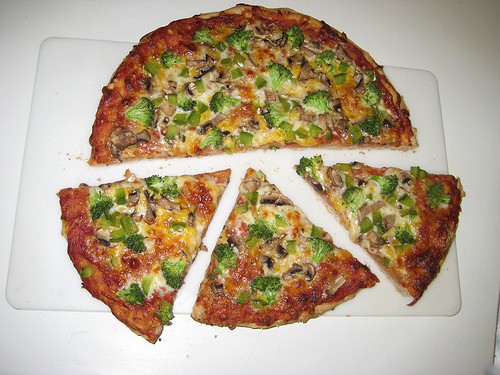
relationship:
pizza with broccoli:
[299, 157, 459, 304] [371, 172, 399, 195]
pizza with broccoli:
[299, 157, 459, 304] [426, 180, 451, 205]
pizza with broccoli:
[299, 157, 459, 304] [343, 185, 364, 209]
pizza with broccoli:
[299, 157, 459, 304] [300, 156, 320, 178]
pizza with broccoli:
[299, 157, 459, 304] [397, 226, 413, 246]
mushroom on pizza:
[306, 262, 316, 281] [190, 167, 380, 329]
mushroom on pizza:
[262, 238, 287, 258] [190, 167, 380, 329]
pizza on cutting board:
[299, 157, 459, 304] [5, 34, 462, 319]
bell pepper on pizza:
[186, 112, 202, 129] [75, 4, 407, 168]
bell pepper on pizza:
[167, 93, 180, 106] [75, 4, 407, 168]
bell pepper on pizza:
[144, 61, 160, 75] [75, 4, 407, 168]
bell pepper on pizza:
[163, 125, 179, 140] [75, 4, 407, 168]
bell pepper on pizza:
[195, 77, 204, 95] [75, 4, 407, 168]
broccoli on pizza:
[300, 156, 320, 178] [299, 157, 459, 304]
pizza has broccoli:
[299, 157, 459, 304] [343, 185, 364, 209]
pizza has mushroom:
[190, 167, 380, 329] [306, 262, 316, 281]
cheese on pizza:
[148, 215, 177, 251] [54, 166, 230, 343]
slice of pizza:
[30, 147, 218, 345] [54, 166, 230, 343]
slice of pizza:
[190, 167, 380, 329] [58, 5, 465, 347]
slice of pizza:
[301, 147, 467, 295] [58, 5, 465, 347]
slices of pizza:
[205, 142, 471, 344] [215, 152, 454, 356]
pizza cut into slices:
[90, 10, 452, 327] [24, 163, 492, 344]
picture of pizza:
[45, 11, 480, 365] [119, 13, 399, 142]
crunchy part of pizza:
[58, 180, 110, 261] [44, 151, 226, 351]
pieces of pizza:
[11, 5, 489, 356] [75, 4, 407, 168]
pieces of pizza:
[11, 5, 489, 356] [299, 157, 459, 304]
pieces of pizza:
[11, 5, 489, 356] [190, 167, 380, 329]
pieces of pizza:
[11, 5, 489, 356] [54, 166, 230, 343]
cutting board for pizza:
[5, 34, 462, 319] [58, 5, 465, 347]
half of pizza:
[85, 5, 419, 163] [58, 5, 465, 347]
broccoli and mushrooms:
[215, 67, 339, 125] [176, 73, 296, 140]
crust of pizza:
[191, 168, 378, 326] [58, 5, 465, 347]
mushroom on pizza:
[251, 235, 293, 261] [58, 5, 465, 347]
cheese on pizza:
[156, 212, 197, 249] [58, 5, 465, 347]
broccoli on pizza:
[342, 167, 404, 215] [58, 5, 465, 347]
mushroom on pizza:
[251, 235, 293, 261] [299, 157, 459, 304]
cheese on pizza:
[156, 212, 197, 249] [299, 157, 459, 304]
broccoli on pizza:
[342, 167, 404, 215] [299, 157, 459, 304]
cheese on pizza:
[91, 172, 221, 301] [54, 166, 230, 343]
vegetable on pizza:
[300, 89, 332, 116] [75, 4, 407, 168]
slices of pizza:
[51, 151, 474, 351] [58, 5, 465, 347]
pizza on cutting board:
[58, 5, 465, 347] [5, 34, 462, 319]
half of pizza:
[58, 162, 463, 334] [58, 5, 465, 347]